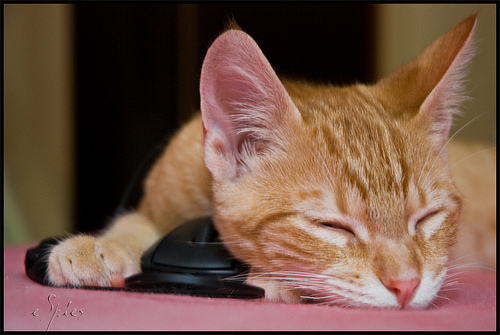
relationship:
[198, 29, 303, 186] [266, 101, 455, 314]
ear on cat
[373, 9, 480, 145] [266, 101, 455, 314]
ear on cat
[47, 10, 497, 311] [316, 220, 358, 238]
cat has closed eye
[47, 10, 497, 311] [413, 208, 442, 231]
cat has closed eye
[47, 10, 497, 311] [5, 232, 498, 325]
cat on surface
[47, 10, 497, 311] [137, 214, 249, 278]
cat sleeping next to mouse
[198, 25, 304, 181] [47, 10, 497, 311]
ear on cat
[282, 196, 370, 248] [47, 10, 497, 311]
closed eye on cat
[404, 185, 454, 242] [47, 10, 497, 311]
closed eye on cat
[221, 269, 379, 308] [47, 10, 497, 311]
whisker on cat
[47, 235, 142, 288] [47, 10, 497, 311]
paw on cat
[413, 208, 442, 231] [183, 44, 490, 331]
closed eye on cat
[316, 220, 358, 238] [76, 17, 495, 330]
closed eye on cat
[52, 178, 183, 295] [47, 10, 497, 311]
leg on cat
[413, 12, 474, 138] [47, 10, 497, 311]
ear on cat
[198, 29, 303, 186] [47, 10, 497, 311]
ear on cat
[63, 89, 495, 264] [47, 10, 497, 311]
fur on cat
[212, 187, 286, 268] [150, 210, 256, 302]
right cheek on mouse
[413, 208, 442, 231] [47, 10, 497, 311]
closed eye of cat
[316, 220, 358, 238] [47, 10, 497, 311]
closed eye of cat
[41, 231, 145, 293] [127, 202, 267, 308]
paw surrounding mouse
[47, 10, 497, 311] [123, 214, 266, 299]
cat leaning on black mouse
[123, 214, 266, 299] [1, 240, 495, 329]
black mouse on pad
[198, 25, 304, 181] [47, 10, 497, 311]
ear of cat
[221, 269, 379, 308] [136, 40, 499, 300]
whisker of cat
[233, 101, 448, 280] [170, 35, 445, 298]
face of cat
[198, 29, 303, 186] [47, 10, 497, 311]
ear of cat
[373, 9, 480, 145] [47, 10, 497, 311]
ear of cat